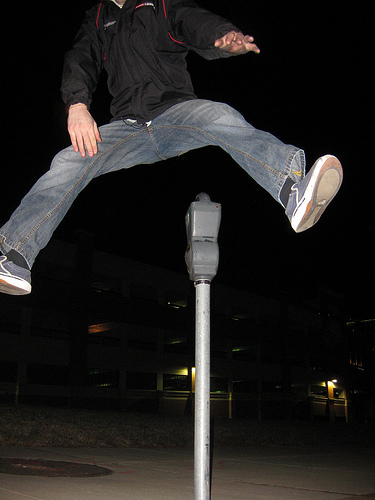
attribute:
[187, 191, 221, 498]
meter — grey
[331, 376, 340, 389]
lights — on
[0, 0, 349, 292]
person — jumping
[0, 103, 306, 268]
pants — blue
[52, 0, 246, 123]
jacket — black, red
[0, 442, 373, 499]
road — brown, pale, cement, cemented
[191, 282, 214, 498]
pole — grey, metal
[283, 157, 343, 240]
shoe — blue, white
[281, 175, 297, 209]
socks — black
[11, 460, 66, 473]
graffiti — red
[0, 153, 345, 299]
shoes — canvas, blue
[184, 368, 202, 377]
porchlight — on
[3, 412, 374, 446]
grass — dead, brown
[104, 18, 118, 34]
lettering — white